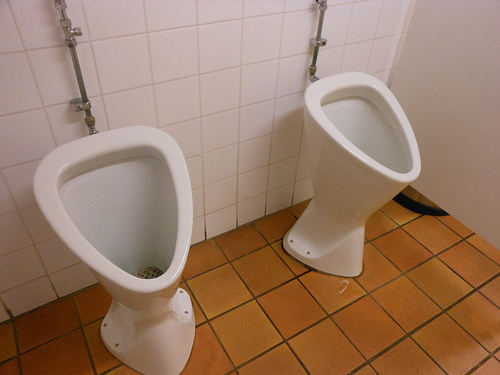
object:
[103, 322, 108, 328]
screw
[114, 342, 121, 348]
screw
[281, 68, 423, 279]
toilet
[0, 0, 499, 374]
restroom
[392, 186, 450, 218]
silver can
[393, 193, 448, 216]
can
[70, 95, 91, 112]
bracket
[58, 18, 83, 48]
bracket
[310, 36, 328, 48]
bracket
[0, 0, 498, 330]
wall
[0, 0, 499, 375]
stall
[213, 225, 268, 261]
tile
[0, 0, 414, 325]
tiles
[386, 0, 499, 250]
divider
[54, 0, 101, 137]
pole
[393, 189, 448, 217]
trashcan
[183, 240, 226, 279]
tile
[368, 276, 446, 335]
grout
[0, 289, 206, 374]
tiles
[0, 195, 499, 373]
floor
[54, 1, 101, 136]
pipe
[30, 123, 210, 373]
urinal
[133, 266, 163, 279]
drain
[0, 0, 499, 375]
bathroom